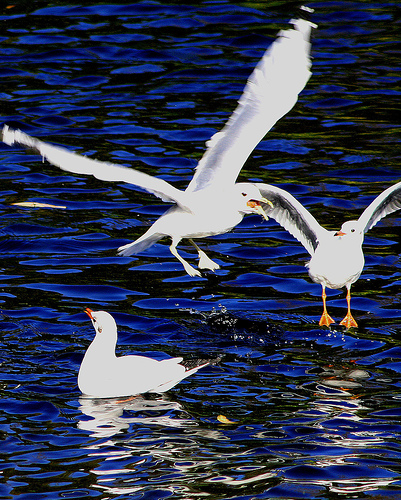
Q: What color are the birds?
A: White.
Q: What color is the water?
A: Blue.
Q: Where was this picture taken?
A: A lake.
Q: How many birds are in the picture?
A: Three.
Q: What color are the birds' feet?
A: Orange.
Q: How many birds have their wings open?
A: Two.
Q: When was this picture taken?
A: During the day.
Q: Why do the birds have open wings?
A: They are flying.